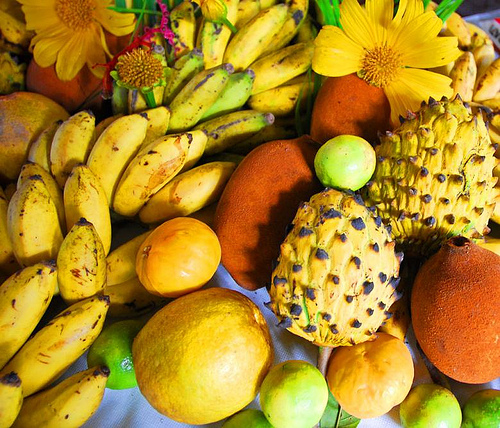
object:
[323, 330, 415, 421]
fruit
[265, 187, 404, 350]
fruit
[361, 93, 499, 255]
fruit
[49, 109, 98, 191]
fruit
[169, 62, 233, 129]
fruit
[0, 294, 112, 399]
banana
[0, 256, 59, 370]
banana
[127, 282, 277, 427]
orange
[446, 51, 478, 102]
fruits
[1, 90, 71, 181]
orange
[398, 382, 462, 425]
fruit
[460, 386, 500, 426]
fruit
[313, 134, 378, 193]
fruit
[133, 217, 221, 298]
fruit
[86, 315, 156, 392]
fruit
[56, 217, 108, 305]
banana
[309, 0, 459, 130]
flower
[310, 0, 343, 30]
green leaves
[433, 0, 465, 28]
green leaves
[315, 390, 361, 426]
green leaves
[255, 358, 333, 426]
fruit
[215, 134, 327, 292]
durians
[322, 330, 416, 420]
orange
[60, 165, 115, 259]
banana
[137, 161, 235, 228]
banana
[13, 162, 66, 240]
banana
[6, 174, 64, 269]
banana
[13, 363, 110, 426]
banana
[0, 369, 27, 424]
banana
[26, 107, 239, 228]
bunch